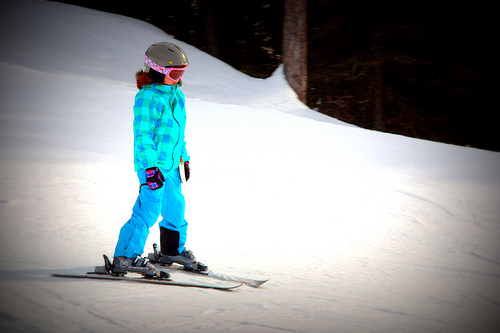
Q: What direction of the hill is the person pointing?
A: Downhill.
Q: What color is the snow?
A: White.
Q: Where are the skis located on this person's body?
A: Their feet.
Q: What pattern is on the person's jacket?
A: Checkered.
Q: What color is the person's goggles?
A: Pink.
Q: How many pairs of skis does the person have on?
A: 1.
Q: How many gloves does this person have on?
A: 2.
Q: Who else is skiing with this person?
A: Nobody.